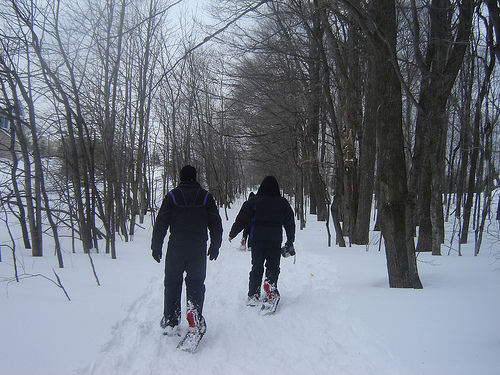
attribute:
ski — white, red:
[178, 314, 210, 358]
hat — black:
[178, 165, 195, 182]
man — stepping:
[231, 181, 325, 261]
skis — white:
[126, 291, 227, 365]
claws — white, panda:
[293, 237, 330, 302]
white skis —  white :
[152, 277, 293, 359]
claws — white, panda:
[170, 308, 210, 359]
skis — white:
[174, 267, 290, 357]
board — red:
[150, 279, 295, 367]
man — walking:
[234, 170, 302, 315]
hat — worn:
[151, 146, 193, 188]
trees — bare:
[298, 10, 428, 292]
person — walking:
[229, 175, 295, 304]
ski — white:
[257, 292, 279, 317]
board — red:
[187, 309, 195, 329]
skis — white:
[133, 135, 326, 373]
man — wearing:
[147, 158, 231, 350]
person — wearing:
[148, 160, 226, 340]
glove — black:
[205, 243, 220, 261]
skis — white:
[168, 230, 362, 282]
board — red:
[117, 267, 247, 357]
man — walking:
[145, 160, 228, 358]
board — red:
[146, 331, 227, 375]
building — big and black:
[72, 183, 156, 355]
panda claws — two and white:
[192, 274, 306, 370]